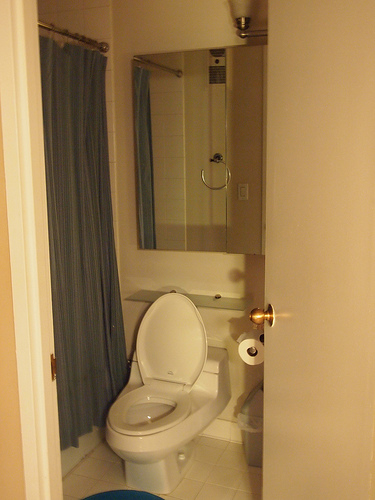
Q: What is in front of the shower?
A: Curtain.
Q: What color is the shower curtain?
A: Blue.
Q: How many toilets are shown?
A: One.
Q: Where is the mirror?
A: Wall.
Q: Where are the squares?
A: Floor.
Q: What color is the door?
A: Tan.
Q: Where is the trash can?
A: Right side of toilet.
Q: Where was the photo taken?
A: In a bathroom.